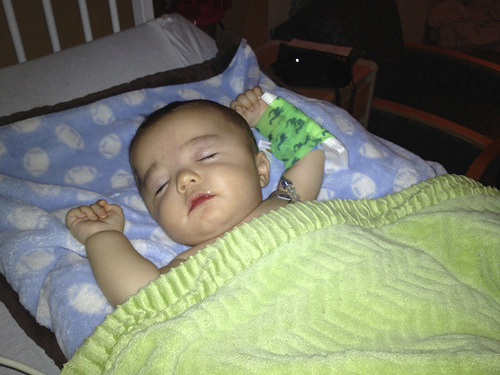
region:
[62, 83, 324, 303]
Baby with an IV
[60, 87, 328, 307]
Baby sleeping in a bed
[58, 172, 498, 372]
Light green baby blanket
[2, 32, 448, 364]
Baby blanket with football pattern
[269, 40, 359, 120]
Black corded telephone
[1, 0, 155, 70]
White metal headboard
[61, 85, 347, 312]
Sick baby sleeping in a bed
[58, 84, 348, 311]
Baby sleeping in the hospital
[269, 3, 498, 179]
Dark hospital armchair with wood arms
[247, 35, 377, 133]
Wood hospital stand with drawers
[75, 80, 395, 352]
a baby laying in a bed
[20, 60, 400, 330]
a baby laying on a pillow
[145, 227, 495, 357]
a green blanket on the baby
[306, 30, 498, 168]
a chair next to the end table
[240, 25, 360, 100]
an end table next to the bed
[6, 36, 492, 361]
a bed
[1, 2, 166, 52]
a white headboard on the bed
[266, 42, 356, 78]
a black bag on an end table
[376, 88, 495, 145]
the arm of the chair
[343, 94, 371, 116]
a drawer on the table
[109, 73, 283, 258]
head of a person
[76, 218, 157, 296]
arm of a person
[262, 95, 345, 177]
arm of a person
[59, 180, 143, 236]
hand of a person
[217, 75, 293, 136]
hand of a person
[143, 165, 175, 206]
eye of a person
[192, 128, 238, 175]
eye of a person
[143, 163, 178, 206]
an eye of a person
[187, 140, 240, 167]
an eye of a person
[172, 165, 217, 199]
nose of a person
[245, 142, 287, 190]
ear of a person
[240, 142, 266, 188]
an ear of a person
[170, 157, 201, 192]
nose of a person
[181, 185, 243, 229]
mouth of a person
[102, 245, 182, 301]
an arm of a person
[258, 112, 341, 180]
an arm of a person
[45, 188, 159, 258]
hand of a person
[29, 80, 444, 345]
Baby laying on the bed.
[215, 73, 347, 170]
Cast on a baby's arm.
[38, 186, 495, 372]
Blanket covering a baby.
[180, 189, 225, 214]
Lips of a baby.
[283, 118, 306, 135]
Design on the wrap of a cast.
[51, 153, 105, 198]
Footballs on the blanket.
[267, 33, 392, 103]
Purse on the table.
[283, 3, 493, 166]
Chair in the background.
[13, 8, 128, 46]
Railing of a bed.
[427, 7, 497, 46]
Coat on a chair.